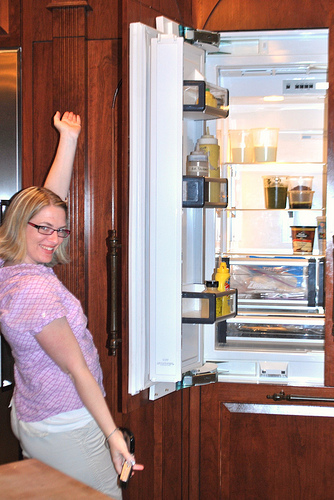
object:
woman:
[0, 112, 144, 500]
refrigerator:
[122, 14, 331, 500]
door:
[180, 384, 333, 500]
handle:
[105, 229, 121, 357]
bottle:
[201, 280, 222, 318]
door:
[127, 13, 219, 413]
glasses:
[37, 225, 71, 239]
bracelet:
[104, 426, 119, 449]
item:
[117, 460, 131, 487]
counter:
[0, 455, 125, 500]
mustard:
[215, 259, 232, 316]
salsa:
[288, 191, 311, 210]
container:
[252, 127, 279, 163]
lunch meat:
[247, 272, 303, 297]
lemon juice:
[198, 87, 214, 107]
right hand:
[109, 428, 144, 481]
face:
[33, 208, 64, 261]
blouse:
[1, 262, 106, 423]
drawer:
[219, 255, 318, 309]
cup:
[263, 176, 289, 209]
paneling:
[34, 35, 125, 416]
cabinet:
[18, 0, 193, 499]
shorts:
[10, 403, 128, 498]